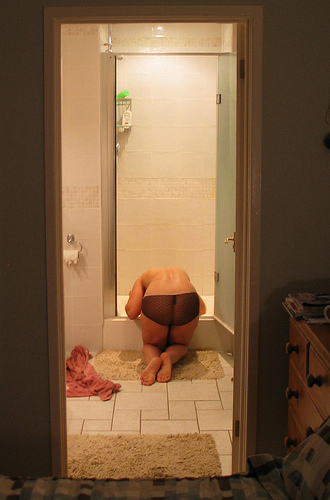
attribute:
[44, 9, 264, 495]
door — opened, bathroom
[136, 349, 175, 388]
feet — bare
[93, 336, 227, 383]
rug — bath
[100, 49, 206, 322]
shower stall — open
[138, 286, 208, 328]
panties — brown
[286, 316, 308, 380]
drawer — wooden, brown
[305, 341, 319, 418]
drawer — wooden, brown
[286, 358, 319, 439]
drawer — wooden, brown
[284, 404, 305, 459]
drawer — wooden, brown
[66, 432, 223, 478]
rug — beige, tan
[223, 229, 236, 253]
knob — golden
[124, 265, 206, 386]
woman — partially clad, kneeling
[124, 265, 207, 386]
someone — sick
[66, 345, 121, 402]
garment — pink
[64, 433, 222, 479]
throw rug — tan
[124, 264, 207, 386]
person — barefoot, throwing up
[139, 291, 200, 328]
underwear — brown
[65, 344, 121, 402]
towel — red, rumpled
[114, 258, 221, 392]
lady — in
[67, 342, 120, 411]
towel — on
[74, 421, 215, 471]
rug — on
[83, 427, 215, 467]
rug — on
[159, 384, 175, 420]
lines — on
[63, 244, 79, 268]
paper — on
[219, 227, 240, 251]
knob — on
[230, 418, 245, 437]
hinge — on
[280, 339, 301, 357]
knob — on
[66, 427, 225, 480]
rug — shaggy, tan, brown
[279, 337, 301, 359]
knob — brown, drawer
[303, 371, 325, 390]
knob — drawer, brown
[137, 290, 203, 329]
underwear — see thru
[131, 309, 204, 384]
legs — bare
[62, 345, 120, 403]
towels — orange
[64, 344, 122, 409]
towel — red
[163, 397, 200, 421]
tile — white